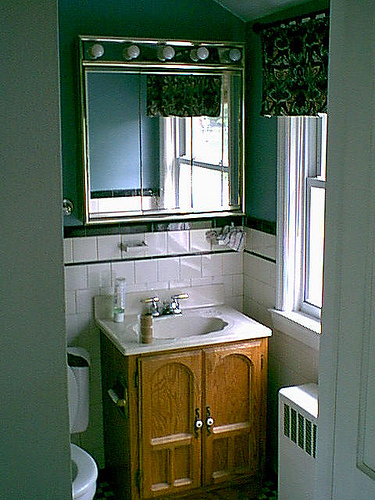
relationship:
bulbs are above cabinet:
[88, 41, 244, 64] [76, 29, 252, 223]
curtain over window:
[252, 6, 332, 119] [286, 114, 325, 328]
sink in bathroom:
[95, 300, 279, 359] [97, 285, 273, 499]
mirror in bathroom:
[81, 67, 246, 223] [2, 1, 374, 498]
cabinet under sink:
[100, 316, 270, 500] [91, 302, 269, 356]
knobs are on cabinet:
[190, 413, 215, 432] [100, 316, 270, 500]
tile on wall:
[127, 248, 201, 285] [64, 237, 253, 300]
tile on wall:
[127, 248, 201, 285] [72, 237, 242, 288]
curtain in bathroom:
[247, 6, 332, 120] [59, 4, 324, 498]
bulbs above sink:
[88, 41, 243, 61] [95, 284, 268, 354]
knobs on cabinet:
[193, 406, 214, 434] [100, 316, 270, 500]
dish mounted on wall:
[113, 239, 155, 259] [68, 225, 237, 302]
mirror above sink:
[81, 67, 246, 223] [94, 276, 274, 363]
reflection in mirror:
[139, 78, 222, 122] [81, 67, 246, 223]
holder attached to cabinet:
[102, 384, 127, 416] [100, 316, 270, 500]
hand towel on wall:
[209, 225, 254, 256] [74, 227, 254, 292]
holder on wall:
[102, 384, 127, 416] [68, 225, 237, 302]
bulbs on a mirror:
[88, 41, 243, 61] [81, 67, 246, 223]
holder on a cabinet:
[102, 384, 127, 416] [100, 316, 270, 500]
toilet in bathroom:
[68, 345, 98, 499] [39, 8, 351, 493]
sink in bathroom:
[95, 300, 279, 359] [2, 1, 374, 498]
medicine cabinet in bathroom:
[78, 33, 245, 219] [2, 1, 374, 498]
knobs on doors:
[193, 406, 214, 434] [138, 347, 261, 499]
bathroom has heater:
[2, 1, 374, 498] [273, 379, 317, 498]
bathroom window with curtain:
[284, 115, 322, 327] [261, 17, 329, 108]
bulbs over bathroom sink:
[88, 41, 243, 61] [138, 297, 232, 338]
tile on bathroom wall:
[127, 248, 201, 285] [69, 220, 276, 363]